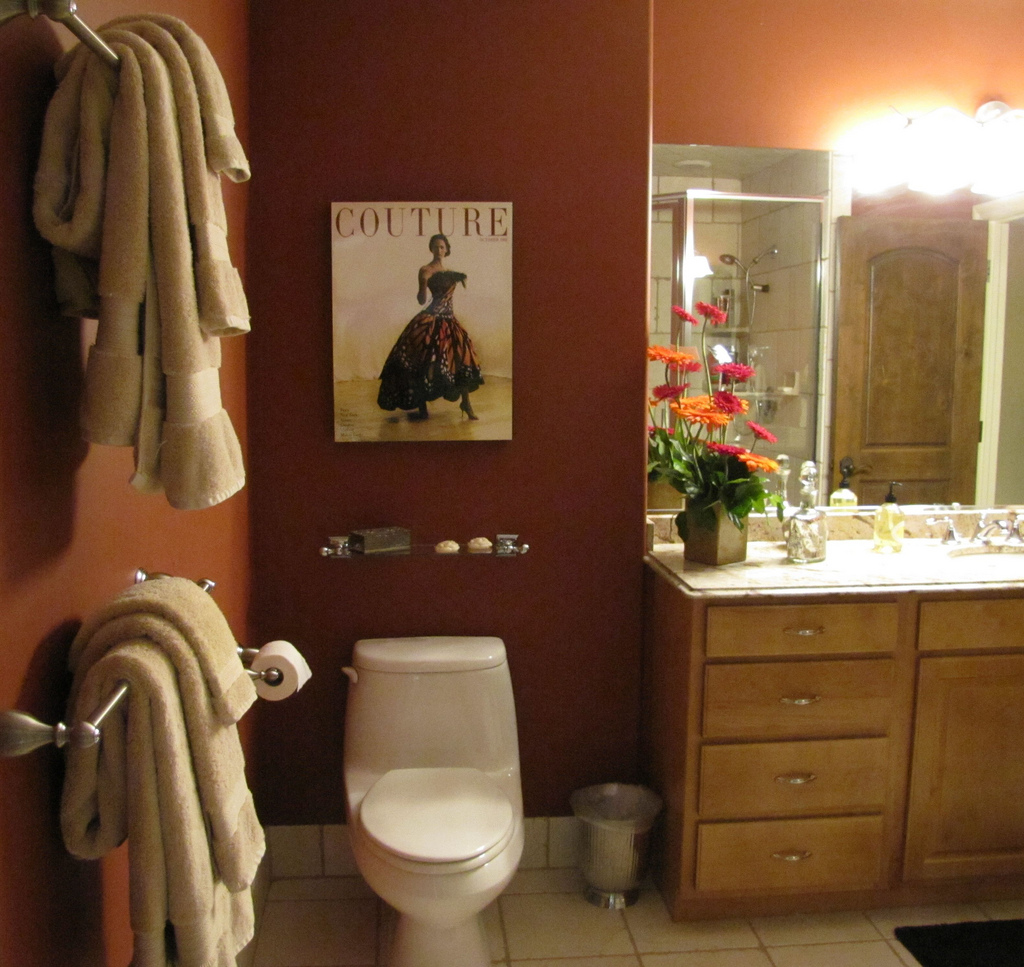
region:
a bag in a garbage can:
[587, 776, 667, 841]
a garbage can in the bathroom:
[555, 765, 688, 930]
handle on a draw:
[779, 676, 857, 725]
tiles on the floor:
[583, 921, 664, 964]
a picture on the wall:
[340, 137, 508, 442]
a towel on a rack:
[75, 542, 192, 818]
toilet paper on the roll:
[242, 614, 312, 722]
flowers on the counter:
[653, 342, 768, 571]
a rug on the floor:
[878, 892, 970, 965]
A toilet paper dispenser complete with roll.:
[247, 635, 314, 702]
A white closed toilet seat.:
[362, 758, 514, 882]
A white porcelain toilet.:
[331, 614, 543, 965]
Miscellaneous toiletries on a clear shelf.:
[309, 519, 544, 568]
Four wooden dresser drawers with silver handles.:
[701, 601, 904, 895]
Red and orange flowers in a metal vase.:
[654, 296, 769, 573]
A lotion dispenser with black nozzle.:
[869, 476, 909, 550]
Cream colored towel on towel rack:
[32, 6, 254, 516]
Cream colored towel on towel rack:
[6, 569, 272, 966]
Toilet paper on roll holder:
[242, 639, 313, 700]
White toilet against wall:
[338, 631, 528, 966]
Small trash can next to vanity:
[572, 776, 664, 916]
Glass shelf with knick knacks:
[316, 521, 531, 569]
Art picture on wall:
[331, 195, 519, 446]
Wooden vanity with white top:
[651, 499, 1022, 924]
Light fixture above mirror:
[821, 89, 1022, 208]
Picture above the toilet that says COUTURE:
[329, 200, 519, 445]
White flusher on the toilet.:
[340, 665, 357, 686]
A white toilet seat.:
[354, 766, 516, 866]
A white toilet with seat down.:
[339, 636, 527, 966]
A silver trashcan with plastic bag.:
[569, 778, 662, 909]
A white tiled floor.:
[260, 879, 1020, 966]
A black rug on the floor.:
[893, 914, 1021, 966]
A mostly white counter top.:
[643, 530, 1021, 595]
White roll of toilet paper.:
[248, 636, 313, 703]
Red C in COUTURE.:
[335, 204, 358, 240]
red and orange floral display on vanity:
[639, 288, 776, 568]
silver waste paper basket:
[565, 771, 660, 912]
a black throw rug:
[878, 911, 1021, 965]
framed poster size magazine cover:
[326, 180, 514, 446]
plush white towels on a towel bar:
[64, 582, 267, 965]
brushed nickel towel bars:
[7, 676, 138, 762]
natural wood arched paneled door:
[832, 205, 982, 507]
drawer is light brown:
[700, 742, 894, 813]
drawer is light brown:
[694, 813, 876, 893]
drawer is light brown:
[912, 651, 1015, 882]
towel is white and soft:
[73, 578, 266, 895]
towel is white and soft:
[62, 650, 255, 965]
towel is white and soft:
[33, 2, 250, 259]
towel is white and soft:
[76, 48, 245, 514]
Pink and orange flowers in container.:
[649, 298, 776, 574]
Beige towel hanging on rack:
[7, 560, 267, 965]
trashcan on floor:
[569, 781, 665, 909]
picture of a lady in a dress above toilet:
[324, 197, 515, 442]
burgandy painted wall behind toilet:
[248, 4, 644, 815]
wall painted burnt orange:
[1, 7, 248, 965]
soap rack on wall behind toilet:
[314, 524, 539, 570]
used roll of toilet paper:
[234, 638, 314, 700]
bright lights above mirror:
[832, 97, 1022, 189]